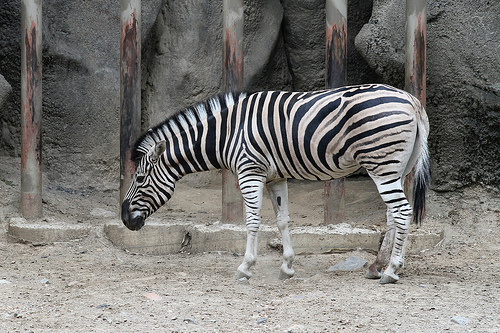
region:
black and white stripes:
[86, 78, 431, 312]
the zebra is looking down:
[104, 126, 191, 252]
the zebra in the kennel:
[116, 78, 436, 283]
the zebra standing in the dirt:
[110, 84, 432, 286]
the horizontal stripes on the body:
[233, 93, 343, 161]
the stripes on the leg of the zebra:
[236, 160, 263, 245]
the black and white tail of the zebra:
[410, 110, 431, 226]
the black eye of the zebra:
[133, 173, 146, 185]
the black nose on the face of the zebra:
[118, 198, 145, 230]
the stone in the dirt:
[322, 247, 370, 282]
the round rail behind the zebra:
[8, 0, 53, 230]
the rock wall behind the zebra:
[39, 0, 122, 182]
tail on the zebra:
[416, 107, 431, 217]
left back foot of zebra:
[382, 205, 412, 286]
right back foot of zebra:
[368, 215, 389, 294]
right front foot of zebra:
[272, 183, 300, 275]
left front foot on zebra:
[227, 187, 264, 288]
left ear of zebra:
[146, 133, 168, 165]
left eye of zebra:
[133, 167, 148, 190]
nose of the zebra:
[113, 196, 133, 227]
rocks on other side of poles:
[39, 12, 122, 172]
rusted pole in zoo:
[13, 2, 58, 217]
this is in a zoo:
[16, 0, 448, 297]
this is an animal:
[11, 45, 463, 270]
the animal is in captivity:
[22, 32, 454, 308]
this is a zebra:
[113, 59, 481, 325]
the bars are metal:
[18, 30, 353, 122]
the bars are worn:
[11, 35, 315, 106]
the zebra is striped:
[146, 74, 405, 273]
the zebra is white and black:
[163, 113, 457, 243]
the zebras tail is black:
[414, 167, 463, 224]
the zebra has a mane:
[105, 109, 234, 141]